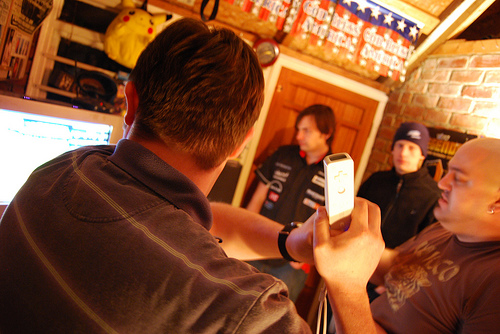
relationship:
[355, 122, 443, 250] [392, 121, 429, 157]
man wearing beanie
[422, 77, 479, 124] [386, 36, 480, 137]
wall made of bricks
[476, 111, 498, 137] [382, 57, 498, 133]
light on bricks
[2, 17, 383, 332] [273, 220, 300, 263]
man wearing watch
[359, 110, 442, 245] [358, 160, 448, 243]
man wearing jacket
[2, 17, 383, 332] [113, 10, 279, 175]
man has brown hair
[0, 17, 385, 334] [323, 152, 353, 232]
man holding remote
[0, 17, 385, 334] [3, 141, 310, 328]
man wearing shirt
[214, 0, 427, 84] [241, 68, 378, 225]
banner hanging above door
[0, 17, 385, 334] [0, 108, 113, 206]
man watching powered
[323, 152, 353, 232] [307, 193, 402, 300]
remote in man's hand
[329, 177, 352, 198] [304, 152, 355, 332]
button on remote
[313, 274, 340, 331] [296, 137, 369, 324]
cord hanging from remote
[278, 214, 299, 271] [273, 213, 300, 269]
watch on wrist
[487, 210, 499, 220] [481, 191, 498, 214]
earring in ear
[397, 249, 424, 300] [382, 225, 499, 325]
design on shirt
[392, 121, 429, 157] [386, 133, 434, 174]
beanie on head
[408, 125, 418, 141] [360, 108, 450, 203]
design on beanie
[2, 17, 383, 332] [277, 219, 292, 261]
man wearing wristwatch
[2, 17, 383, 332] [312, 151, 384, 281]
man playing a video game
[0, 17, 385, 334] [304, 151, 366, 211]
man holding remote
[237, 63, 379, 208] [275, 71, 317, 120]
door made of wood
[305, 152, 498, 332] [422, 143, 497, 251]
man does not have hair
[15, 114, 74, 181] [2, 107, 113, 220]
powered on television screen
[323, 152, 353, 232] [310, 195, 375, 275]
remote in persons hand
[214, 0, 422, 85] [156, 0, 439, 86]
banner on wall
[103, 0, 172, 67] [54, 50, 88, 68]
pikachu hanging on wall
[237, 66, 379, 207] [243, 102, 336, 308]
door behind man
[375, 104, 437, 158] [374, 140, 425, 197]
beanie hat on man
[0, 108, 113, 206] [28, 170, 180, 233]
powered screen behind man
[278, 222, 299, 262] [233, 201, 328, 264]
watch on mans wrist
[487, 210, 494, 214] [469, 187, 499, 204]
earring in mans ear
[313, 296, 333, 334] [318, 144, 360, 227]
cord hanging down from wii remote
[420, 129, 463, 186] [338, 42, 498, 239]
poster on wall